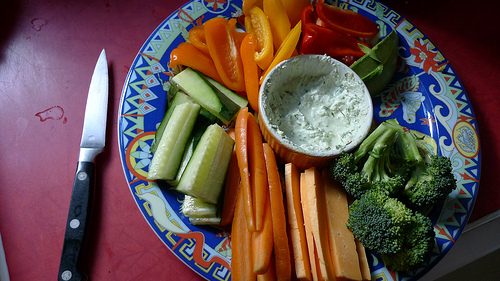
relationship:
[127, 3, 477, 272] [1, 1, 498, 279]
plate on table